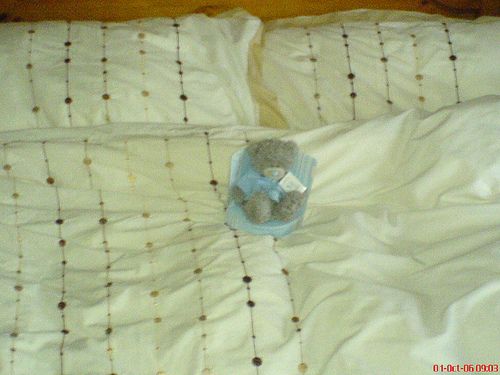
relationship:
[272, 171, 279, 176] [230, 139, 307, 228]
nose on bear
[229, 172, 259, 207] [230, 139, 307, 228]
arm of bear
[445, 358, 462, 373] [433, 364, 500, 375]
letters mixed with letters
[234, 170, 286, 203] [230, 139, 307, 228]
shirt on bear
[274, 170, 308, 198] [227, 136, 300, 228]
tag on bear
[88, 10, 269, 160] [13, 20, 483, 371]
pillow on bed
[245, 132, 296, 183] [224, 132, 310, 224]
head of teddy bear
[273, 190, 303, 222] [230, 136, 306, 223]
foot of teddy bear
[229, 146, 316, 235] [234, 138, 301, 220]
blanket of teddy bear